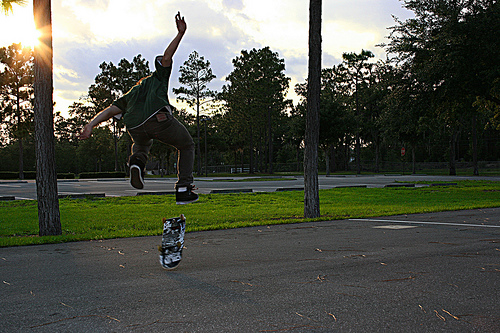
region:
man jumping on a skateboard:
[76, 10, 200, 202]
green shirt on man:
[110, 53, 173, 130]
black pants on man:
[125, 104, 194, 189]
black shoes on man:
[129, 156, 201, 205]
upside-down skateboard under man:
[156, 212, 187, 269]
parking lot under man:
[1, 205, 498, 332]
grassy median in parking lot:
[0, 181, 499, 249]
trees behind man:
[32, 0, 321, 236]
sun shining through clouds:
[11, 16, 42, 49]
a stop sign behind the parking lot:
[400, 145, 406, 155]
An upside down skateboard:
[155, 214, 188, 271]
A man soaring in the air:
[78, 11, 201, 202]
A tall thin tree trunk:
[295, 0, 330, 220]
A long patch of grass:
[0, 180, 497, 249]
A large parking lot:
[2, 163, 494, 200]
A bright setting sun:
[0, 1, 59, 68]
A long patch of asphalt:
[0, 209, 498, 331]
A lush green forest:
[323, 10, 498, 175]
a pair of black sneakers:
[171, 182, 202, 207]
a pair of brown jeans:
[119, 110, 201, 184]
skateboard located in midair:
[157, 203, 227, 310]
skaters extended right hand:
[160, 5, 206, 71]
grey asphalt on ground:
[274, 266, 337, 328]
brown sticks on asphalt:
[414, 295, 466, 324]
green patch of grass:
[235, 196, 284, 209]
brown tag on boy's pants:
[145, 106, 172, 135]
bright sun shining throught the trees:
[3, 30, 52, 73]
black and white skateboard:
[156, 207, 199, 289]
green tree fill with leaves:
[443, 39, 498, 69]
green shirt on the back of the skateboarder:
[129, 84, 176, 107]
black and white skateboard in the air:
[156, 214, 186, 268]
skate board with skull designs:
[158, 214, 187, 269]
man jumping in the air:
[79, 11, 210, 203]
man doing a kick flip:
[76, 11, 197, 201]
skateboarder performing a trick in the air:
[76, 6, 223, 270]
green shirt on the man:
[109, 53, 174, 129]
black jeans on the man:
[125, 104, 195, 186]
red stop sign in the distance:
[398, 147, 409, 159]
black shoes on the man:
[127, 160, 198, 201]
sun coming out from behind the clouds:
[12, 23, 51, 53]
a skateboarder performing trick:
[77, 9, 199, 266]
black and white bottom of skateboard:
[159, 215, 184, 266]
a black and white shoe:
[126, 161, 145, 191]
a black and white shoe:
[174, 189, 199, 202]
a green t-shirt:
[109, 54, 173, 133]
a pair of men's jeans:
[126, 110, 196, 184]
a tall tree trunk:
[304, 0, 324, 220]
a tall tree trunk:
[32, 0, 61, 237]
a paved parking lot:
[1, 175, 426, 201]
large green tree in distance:
[218, 44, 293, 176]